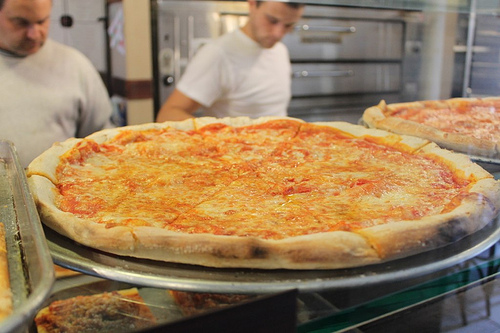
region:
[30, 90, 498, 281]
a crusty cheese pizza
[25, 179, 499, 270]
a silver pan under a pizza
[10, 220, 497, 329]
a glass shelf holding a silver pan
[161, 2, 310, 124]
a man in a white shirt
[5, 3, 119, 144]
a man in a light grey shirt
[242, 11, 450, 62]
a pizza oven door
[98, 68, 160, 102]
a chair rail on a wall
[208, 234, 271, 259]
burn marks on a pizza crust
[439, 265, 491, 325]
legs of a chair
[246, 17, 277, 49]
a beard on a man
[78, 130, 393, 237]
this is a pizza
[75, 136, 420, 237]
the pizza is big in size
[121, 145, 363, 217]
the pizza is spicy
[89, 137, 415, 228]
the pizza is flat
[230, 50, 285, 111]
the t shirt is white in color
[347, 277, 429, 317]
the table is of glass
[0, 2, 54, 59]
the head is facing down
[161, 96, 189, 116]
the hand is folded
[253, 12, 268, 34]
the man is light skinned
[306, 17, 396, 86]
the oven is metallic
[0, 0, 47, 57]
Head of man on the right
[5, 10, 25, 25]
Right eye of man on the right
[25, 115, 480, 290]
Quiche sitting on gray tray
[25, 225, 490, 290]
Gray tray with quiche sitting on it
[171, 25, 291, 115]
white tee shirt of man on the left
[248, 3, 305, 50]
Head of man on the left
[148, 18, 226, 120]
Right arm/shoulder of man on the left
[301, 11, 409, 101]
Stainless steel pizza oven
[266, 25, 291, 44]
Nose of man on the left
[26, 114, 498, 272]
pizza with cheese and red sauce with tan crust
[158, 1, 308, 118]
man in white t-shirt working in commercial kitchen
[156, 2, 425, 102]
two metal oven doors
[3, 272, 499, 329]
pizza shop glass display window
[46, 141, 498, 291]
metal pizza pan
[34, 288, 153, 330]
red sauce covered pizza slice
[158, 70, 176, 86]
black metal knob on pizza oven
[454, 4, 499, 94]
standing silver trays in commercial kitchen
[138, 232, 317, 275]
cooked tan pizza crust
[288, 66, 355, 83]
metal handle on oven door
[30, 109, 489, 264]
large cheese pizza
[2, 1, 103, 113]
man working in pizzaria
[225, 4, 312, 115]
man working in pizzaria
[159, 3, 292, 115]
man wearing a short sleeve white tshirt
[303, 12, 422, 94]
large metal pizza oven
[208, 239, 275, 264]
section of crisp pizza crust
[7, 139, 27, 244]
steel pan for cooking pizza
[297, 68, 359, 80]
handle of pizza oven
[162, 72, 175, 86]
knob on pizza oven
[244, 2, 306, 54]
man with facial hair